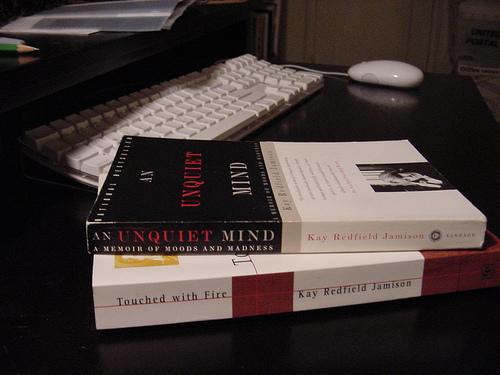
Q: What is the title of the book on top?
A: An unquiet mind.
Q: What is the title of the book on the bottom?
A: Touched with Fire.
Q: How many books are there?
A: 2.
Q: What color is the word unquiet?
A: Red.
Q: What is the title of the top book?
A: An Unquiet Mind.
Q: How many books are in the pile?
A: 2.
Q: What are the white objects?
A: A pile of papers.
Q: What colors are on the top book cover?
A: Red, white, black, and grey.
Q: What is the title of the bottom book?
A: Touched with Fire.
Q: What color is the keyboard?
A: White and Silver.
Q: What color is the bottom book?
A: Red, White, and yellow.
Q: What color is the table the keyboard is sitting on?
A: Black.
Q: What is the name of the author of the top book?
A: Kay Redfield Jamison.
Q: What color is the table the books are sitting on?
A: Black.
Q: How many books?
A: Two.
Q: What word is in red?
A: UNQUIET.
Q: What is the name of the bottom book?
A: Touched with Fire.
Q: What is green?
A: Pencil.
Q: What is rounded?
A: Mouse.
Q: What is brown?
A: Desk.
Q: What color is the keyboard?
A: White.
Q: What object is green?
A: Pencil.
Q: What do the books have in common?
A: Same Author.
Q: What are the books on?
A: Desk.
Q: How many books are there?
A: Two.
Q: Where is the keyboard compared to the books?
A: Behind.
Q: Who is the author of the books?
A: Kay Redfield Jamison.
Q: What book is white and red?
A: Touched with Fire.